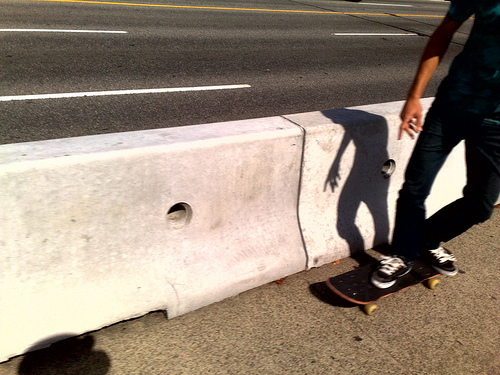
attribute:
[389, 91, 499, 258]
jeans — black, tight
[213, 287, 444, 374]
sidewalk — concrete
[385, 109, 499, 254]
pants — black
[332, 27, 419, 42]
line — divider, white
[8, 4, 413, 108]
highway — black, paved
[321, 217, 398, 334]
skateboard — black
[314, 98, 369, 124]
head — skater's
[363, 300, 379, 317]
wheel — yellow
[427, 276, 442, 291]
wheel — yellow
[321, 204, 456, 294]
sneakers — black, white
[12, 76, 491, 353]
barrier — concrete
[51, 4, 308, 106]
pavement — black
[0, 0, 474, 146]
street — three lane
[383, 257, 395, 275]
laces — white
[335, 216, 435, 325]
shoes — black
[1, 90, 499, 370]
divider — concrete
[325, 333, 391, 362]
flecks — stone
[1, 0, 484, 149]
lines — white